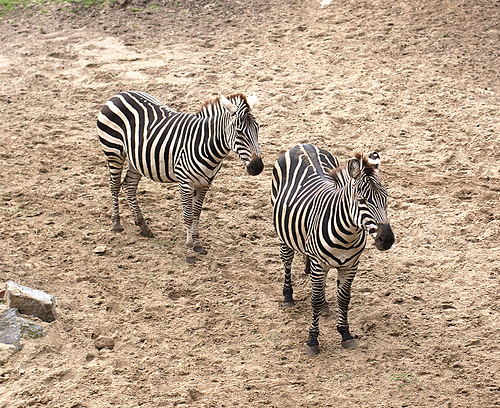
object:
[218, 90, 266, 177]
head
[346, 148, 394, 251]
head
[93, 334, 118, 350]
rock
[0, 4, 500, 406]
field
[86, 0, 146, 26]
patch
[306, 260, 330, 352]
leg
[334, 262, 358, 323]
leg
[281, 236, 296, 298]
leg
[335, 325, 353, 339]
area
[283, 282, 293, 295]
area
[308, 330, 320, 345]
area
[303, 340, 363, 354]
hooves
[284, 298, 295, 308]
hooves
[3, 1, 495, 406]
zebra habitat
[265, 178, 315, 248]
belly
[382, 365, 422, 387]
grass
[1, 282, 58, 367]
rocks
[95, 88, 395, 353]
zebras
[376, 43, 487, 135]
ground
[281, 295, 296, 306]
black feet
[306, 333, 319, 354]
black feet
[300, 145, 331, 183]
long stripe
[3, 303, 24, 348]
rock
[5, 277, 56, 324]
rock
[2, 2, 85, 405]
ground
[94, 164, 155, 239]
hind legs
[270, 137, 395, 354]
zebra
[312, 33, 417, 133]
grass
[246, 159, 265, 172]
nose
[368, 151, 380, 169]
ear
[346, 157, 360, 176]
ear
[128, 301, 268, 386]
sand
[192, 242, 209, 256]
foot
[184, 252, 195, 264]
foot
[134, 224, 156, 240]
foot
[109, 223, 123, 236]
foot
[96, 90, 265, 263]
zebra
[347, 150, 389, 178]
ears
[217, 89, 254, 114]
ears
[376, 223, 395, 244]
nose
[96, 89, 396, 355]
zebra's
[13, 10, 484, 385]
sand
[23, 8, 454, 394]
dirt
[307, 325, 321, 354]
feet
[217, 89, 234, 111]
ear